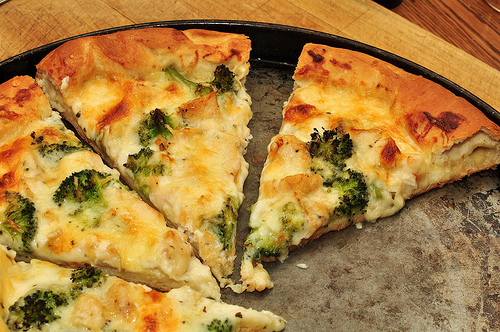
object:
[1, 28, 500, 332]
pizza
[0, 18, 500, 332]
tray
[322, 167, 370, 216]
broccoli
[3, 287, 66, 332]
broccoli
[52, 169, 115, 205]
broccoli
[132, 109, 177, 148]
broccoli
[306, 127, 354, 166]
broccoli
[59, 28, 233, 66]
crust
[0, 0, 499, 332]
table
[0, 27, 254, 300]
slice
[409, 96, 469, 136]
crust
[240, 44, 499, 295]
slice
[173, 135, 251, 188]
cheese